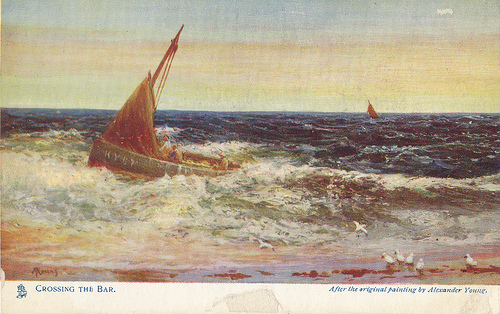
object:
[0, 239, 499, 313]
beach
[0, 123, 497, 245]
waves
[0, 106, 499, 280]
ocean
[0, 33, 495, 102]
cloud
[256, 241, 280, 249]
birds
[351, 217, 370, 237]
bird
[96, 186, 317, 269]
water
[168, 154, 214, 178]
edge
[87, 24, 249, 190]
boat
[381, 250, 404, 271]
birds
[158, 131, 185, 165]
people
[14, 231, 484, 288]
shore